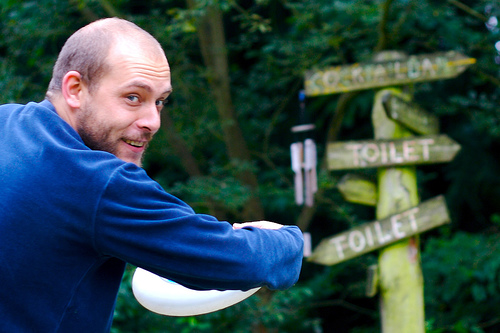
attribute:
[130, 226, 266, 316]
frisbee is in hand — white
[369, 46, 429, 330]
post is wooden — whimsical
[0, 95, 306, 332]
shirt is blue — blue , long sleeved 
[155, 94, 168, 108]
eye is blue — blue 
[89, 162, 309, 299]
sleeve is long — blue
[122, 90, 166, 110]
eyes are blue — pair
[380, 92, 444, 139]
arrow is wooden — directional